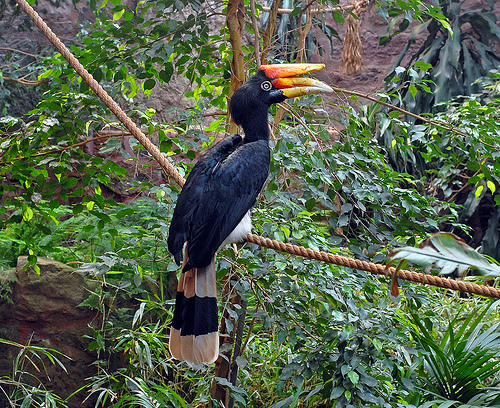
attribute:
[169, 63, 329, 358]
bird — black, white, large, color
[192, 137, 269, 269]
wing — Black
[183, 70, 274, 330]
bird — large, perched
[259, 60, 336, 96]
beak — orange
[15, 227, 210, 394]
rock — grey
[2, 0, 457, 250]
dirt — covering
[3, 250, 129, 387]
rock — beaten, weathered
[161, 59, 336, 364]
hornbill — Black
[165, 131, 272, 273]
wings — black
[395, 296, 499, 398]
plant — tall, grass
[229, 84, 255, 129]
head — black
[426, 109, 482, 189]
plant — long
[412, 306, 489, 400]
plant — long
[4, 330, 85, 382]
plant — long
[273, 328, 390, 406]
plant — long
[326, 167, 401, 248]
plant — long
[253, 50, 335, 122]
beak — Yellow, Red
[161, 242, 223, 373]
tail feathers — black, stripe, white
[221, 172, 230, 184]
feather — black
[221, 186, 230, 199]
feather — black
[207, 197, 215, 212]
feather — black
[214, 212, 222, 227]
feather — black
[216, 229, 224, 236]
feather — black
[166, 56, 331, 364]
horn-bill — young, black, white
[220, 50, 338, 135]
head — round, black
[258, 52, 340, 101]
beak — orange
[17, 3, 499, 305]
rope — brown, twisted, horizontal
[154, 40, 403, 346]
hornbill — long-tailed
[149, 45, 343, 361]
beaked hornbill — orange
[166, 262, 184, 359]
tail feather — long, black, white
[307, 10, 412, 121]
dirt — Brown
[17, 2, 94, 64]
dirt — Brown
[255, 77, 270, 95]
eye — blue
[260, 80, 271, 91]
eye — white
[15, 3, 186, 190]
rope — large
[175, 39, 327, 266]
bird — red, orange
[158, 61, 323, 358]
bird — large, black, white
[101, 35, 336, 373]
bird — Black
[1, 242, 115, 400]
rock — gray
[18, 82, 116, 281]
leaves — triangular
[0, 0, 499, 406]
vegetated grounds — green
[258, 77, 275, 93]
ring — yellow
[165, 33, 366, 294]
bird — large, perched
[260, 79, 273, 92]
eyes — rounded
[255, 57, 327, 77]
appendage — orange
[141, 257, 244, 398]
tail feather — tan, tip